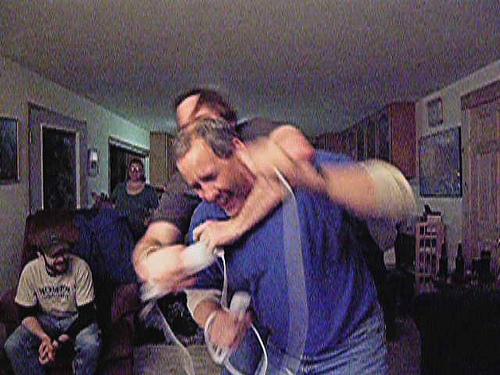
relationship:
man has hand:
[171, 114, 421, 373] [204, 310, 253, 349]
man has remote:
[171, 114, 421, 373] [230, 290, 251, 326]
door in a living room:
[463, 92, 499, 267] [10, 10, 489, 369]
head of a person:
[24, 208, 81, 273] [5, 226, 101, 371]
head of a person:
[124, 158, 147, 185] [128, 159, 143, 180]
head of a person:
[31, 229, 78, 274] [37, 236, 67, 273]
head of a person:
[169, 87, 241, 130] [172, 88, 235, 130]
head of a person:
[164, 119, 253, 226] [174, 121, 255, 214]